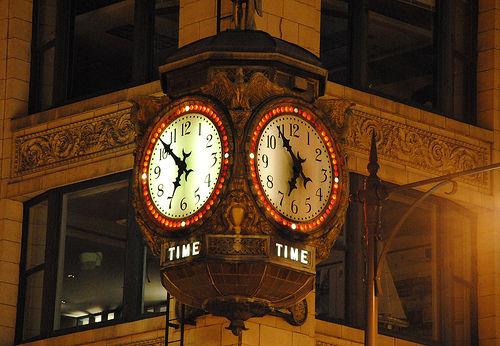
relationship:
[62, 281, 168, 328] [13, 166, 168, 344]
light coming from window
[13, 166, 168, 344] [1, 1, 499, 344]
window on structure of building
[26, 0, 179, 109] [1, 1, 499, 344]
window on structure of building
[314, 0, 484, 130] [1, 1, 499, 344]
window on structure of building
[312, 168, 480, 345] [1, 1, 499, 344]
window on structure of building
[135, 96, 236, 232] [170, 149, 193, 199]
clock has hour hand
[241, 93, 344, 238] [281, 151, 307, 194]
clock has hour hand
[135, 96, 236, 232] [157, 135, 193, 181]
clock has minute hand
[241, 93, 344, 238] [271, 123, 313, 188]
clock has minute hand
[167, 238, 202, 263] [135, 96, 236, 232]
word below clock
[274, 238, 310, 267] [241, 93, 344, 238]
word below clock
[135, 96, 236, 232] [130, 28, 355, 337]
clock part of structure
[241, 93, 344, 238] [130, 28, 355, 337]
clock part of structure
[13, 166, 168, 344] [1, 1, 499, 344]
window part of building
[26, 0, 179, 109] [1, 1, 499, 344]
window part of building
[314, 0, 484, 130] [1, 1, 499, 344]
window part of building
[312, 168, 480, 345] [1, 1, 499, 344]
window part of building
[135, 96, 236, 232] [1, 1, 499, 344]
clock near building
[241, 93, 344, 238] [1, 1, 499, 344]
clock near building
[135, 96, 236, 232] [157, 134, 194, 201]
clock reads time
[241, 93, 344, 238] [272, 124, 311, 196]
clock reads time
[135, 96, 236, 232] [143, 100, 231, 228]
clock has orange ring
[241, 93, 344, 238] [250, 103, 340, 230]
clock has orange ring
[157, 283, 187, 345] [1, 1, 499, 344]
ladder on side of building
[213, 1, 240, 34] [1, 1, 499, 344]
ladder on side of building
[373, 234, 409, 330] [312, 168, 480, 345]
sail boat inside of window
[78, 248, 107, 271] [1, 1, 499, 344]
fire alarm inside of building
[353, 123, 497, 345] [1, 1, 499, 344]
sign holder beside building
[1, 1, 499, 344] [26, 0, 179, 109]
building has window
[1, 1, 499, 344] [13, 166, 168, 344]
building has window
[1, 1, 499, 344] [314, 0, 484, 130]
building has window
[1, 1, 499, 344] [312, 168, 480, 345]
building has window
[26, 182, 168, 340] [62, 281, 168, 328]
office has lights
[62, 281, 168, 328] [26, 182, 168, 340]
light inside of office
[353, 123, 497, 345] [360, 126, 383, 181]
light pole has point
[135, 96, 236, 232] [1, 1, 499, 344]
clock beside building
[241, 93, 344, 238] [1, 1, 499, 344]
clock beside building